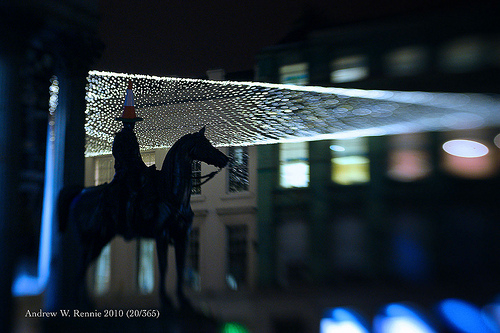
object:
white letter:
[83, 309, 91, 319]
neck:
[158, 147, 195, 193]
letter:
[31, 310, 38, 318]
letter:
[57, 309, 69, 315]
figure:
[101, 83, 147, 242]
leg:
[173, 240, 187, 297]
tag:
[23, 305, 163, 321]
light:
[441, 137, 490, 159]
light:
[328, 66, 371, 86]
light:
[330, 154, 374, 187]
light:
[278, 160, 312, 189]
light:
[371, 302, 438, 330]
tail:
[53, 183, 73, 237]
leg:
[155, 240, 170, 304]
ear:
[197, 125, 208, 137]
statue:
[49, 79, 231, 321]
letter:
[95, 310, 103, 318]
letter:
[71, 308, 81, 318]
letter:
[23, 307, 33, 318]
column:
[43, 66, 88, 312]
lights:
[276, 161, 310, 191]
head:
[186, 125, 230, 171]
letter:
[48, 310, 58, 318]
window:
[223, 222, 251, 292]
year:
[100, 307, 162, 320]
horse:
[52, 124, 231, 317]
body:
[50, 181, 196, 242]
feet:
[159, 304, 177, 318]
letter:
[45, 311, 50, 318]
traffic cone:
[113, 80, 145, 122]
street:
[0, 276, 499, 327]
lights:
[384, 149, 433, 185]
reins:
[187, 167, 222, 189]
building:
[2, 0, 497, 332]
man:
[110, 82, 155, 243]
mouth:
[214, 157, 229, 170]